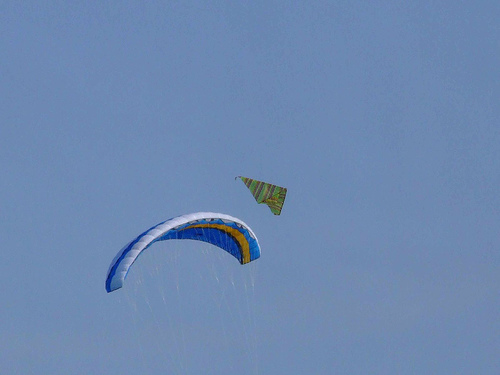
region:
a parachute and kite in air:
[51, 82, 392, 374]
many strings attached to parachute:
[83, 193, 313, 373]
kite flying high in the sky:
[208, 62, 488, 374]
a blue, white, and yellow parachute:
[63, 160, 393, 374]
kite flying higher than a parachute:
[63, 129, 393, 371]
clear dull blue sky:
[68, 21, 434, 337]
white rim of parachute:
[111, 202, 289, 315]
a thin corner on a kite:
[230, 167, 295, 223]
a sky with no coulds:
[22, 12, 390, 356]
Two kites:
[96, 138, 335, 295]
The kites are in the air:
[71, 119, 341, 304]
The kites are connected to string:
[133, 248, 316, 373]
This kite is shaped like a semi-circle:
[81, 200, 288, 303]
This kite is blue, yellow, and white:
[80, 198, 266, 317]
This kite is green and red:
[234, 160, 297, 225]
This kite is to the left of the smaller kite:
[73, 199, 273, 294]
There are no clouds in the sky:
[10, 17, 485, 347]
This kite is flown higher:
[231, 150, 303, 213]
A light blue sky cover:
[351, 187, 498, 372]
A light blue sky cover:
[128, 272, 300, 370]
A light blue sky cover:
[1, 222, 79, 370]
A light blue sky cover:
[15, 52, 185, 179]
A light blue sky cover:
[190, 23, 285, 147]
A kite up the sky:
[237, 164, 319, 231]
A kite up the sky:
[97, 193, 264, 303]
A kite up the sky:
[17, 7, 184, 77]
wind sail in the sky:
[100, 205, 266, 295]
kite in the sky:
[230, 168, 295, 220]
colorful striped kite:
[238, 163, 290, 225]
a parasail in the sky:
[95, 204, 267, 291]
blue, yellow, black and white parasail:
[95, 206, 257, 283]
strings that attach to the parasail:
[120, 225, 274, 373]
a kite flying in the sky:
[230, 164, 290, 219]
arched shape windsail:
[101, 205, 263, 293]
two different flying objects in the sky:
[97, 162, 292, 297]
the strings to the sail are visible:
[131, 225, 258, 374]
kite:
[60, 206, 258, 303]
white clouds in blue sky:
[30, 38, 95, 93]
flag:
[232, 165, 306, 212]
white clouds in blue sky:
[345, 252, 420, 294]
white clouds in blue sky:
[287, 315, 342, 369]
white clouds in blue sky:
[174, 329, 209, 366]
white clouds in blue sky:
[157, 288, 205, 332]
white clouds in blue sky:
[230, 51, 254, 72]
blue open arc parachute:
[91, 197, 261, 316]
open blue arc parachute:
[97, 197, 276, 340]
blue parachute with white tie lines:
[57, 201, 289, 311]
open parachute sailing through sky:
[82, 192, 279, 334]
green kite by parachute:
[221, 153, 303, 218]